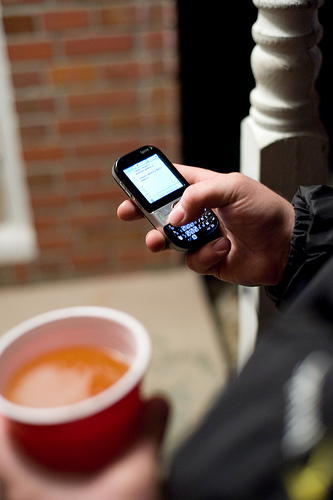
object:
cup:
[0, 302, 151, 476]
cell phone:
[111, 143, 222, 254]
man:
[0, 164, 332, 499]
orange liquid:
[5, 346, 107, 400]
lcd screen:
[123, 153, 184, 204]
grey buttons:
[155, 209, 169, 224]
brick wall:
[0, 1, 180, 287]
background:
[1, 1, 330, 467]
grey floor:
[1, 259, 224, 476]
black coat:
[164, 184, 332, 499]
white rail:
[235, 0, 330, 374]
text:
[135, 164, 164, 182]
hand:
[0, 396, 167, 498]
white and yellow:
[283, 353, 333, 493]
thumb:
[165, 174, 234, 228]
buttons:
[192, 235, 197, 240]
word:
[139, 147, 150, 154]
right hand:
[117, 163, 295, 290]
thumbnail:
[168, 203, 185, 227]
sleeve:
[264, 185, 332, 313]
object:
[184, 237, 230, 273]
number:
[191, 234, 197, 242]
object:
[43, 9, 91, 32]